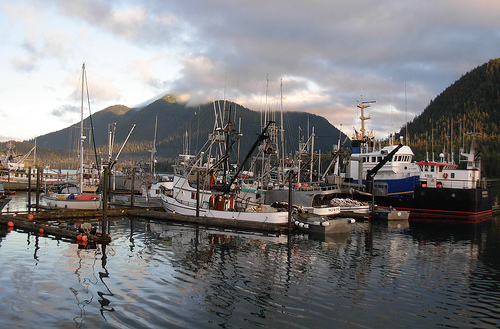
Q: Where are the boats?
A: At the dock.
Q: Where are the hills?
A: Alongside the water.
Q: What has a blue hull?
A: A large fishing boat.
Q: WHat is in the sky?
A: Fluffy white clouds.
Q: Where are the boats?
A: In the water.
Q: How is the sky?
A: Cloudy.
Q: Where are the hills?
A: In the distance.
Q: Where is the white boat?
A: In the water.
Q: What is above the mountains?
A: Clouds.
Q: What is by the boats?
A: Rippling water.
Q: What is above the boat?
A: Trees on hill.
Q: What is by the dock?
A: Engine boat.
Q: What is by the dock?
A: Engine boat.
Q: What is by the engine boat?
A: Ship.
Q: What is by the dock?
A: Rippling water.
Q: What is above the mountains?
A: Clouds.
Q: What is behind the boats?
A: Mountains.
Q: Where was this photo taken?
A: A marina.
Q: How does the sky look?
A: Cloudy.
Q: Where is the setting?
A: In a marina.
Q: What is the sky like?
A: Mostly cloudy.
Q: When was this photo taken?
A: During the daytime.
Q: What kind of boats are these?
A: Small fishing boats.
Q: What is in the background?
A: Mountain.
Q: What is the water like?
A: Calm.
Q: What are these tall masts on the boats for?
A: Sails.